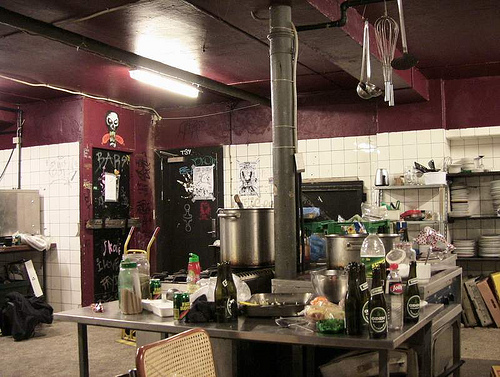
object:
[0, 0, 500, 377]
kitchen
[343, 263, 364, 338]
bottles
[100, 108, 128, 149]
skull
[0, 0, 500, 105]
ceiling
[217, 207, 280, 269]
pot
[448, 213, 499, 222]
shelf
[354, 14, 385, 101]
ladels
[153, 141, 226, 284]
door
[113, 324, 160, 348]
cart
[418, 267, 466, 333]
oven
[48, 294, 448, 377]
counter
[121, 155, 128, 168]
figure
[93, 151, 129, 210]
graffiti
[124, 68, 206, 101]
lamp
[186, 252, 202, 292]
bottle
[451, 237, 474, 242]
plates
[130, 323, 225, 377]
chair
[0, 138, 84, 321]
wall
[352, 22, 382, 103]
ladles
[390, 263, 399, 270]
cap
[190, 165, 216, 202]
poster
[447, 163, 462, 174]
dishes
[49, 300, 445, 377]
table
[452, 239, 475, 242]
bowls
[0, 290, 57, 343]
backpack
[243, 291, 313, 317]
pan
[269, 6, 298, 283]
pipe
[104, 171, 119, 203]
paper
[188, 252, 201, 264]
top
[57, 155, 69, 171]
tiles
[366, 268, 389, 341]
bottle